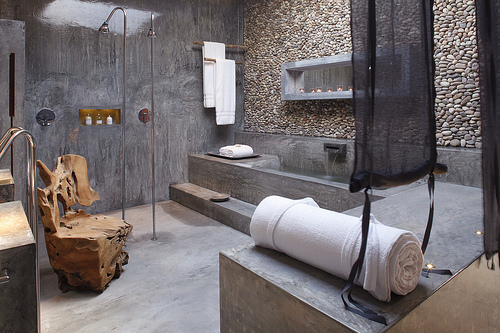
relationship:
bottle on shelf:
[107, 113, 112, 123] [76, 105, 123, 128]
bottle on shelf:
[95, 113, 102, 123] [76, 105, 123, 128]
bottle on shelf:
[82, 113, 93, 125] [76, 105, 123, 128]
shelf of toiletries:
[65, 100, 125, 129] [85, 112, 115, 123]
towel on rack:
[210, 52, 240, 132] [195, 52, 252, 67]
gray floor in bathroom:
[39, 199, 248, 331] [3, 1, 499, 331]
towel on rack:
[202, 55, 235, 126] [199, 53, 244, 65]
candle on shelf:
[296, 87, 306, 94] [278, 40, 424, 101]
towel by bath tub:
[217, 140, 259, 161] [191, 152, 414, 215]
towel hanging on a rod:
[216, 57, 238, 123] [193, 38, 248, 66]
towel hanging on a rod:
[201, 40, 222, 105] [193, 38, 248, 66]